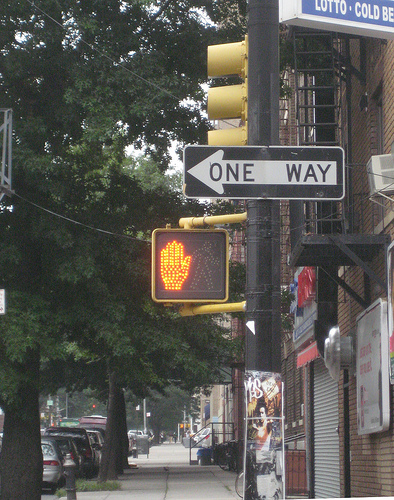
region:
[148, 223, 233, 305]
pedestrian Don't Walk signal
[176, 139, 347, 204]
black and white sign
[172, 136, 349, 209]
black and white rectangular One Way sign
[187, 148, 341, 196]
white arrow pointing left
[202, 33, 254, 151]
yellow traffic signal on pole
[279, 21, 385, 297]
metal fire escape on side of building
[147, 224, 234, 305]
Stop sign for padestrians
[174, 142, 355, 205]
Black and white one way sign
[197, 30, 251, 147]
Traffic signal for vehicles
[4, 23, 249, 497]
Shady trees on the sidewalk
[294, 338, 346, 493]
Metal shutter of the store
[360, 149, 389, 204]
Window airconditioner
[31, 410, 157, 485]
Cars parked near sidewalk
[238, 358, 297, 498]
Poster on black pole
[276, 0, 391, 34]
Store sign for lotto and cold beer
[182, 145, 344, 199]
a one way sign on a post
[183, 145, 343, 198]
a black sign under the traffic lights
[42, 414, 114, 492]
cars parked on the side of the road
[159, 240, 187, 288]
sign of a hand shown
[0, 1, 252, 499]
large green trees lining the street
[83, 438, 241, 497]
a gray, empty sidewalk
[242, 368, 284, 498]
a poster on the side of the post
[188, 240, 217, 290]
a man next to the hand sign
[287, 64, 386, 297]
balcony on the side of the building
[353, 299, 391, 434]
a large white sign on the side of the building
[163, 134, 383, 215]
One of the signs on the pole says "One Way"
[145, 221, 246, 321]
The walk or dont walk sign is lit up with dont walk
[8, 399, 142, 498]
There are cars parked along the curb on this street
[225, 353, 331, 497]
There is a sign with graffiti on it on the pole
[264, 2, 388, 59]
A business is on this corner called Lotto-Cold beer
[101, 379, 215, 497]
The sidewalk is empty of people.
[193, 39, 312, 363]
A stop light is on this pole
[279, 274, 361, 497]
A garage door on the street is steel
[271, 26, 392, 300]
There is a staircase outside of the building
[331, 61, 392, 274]
The building is brick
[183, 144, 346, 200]
a one way traffic sign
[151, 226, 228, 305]
a pedestrian crossing signal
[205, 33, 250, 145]
a traffic light on the post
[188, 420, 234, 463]
a hand rail on the steps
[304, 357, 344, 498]
a security garage door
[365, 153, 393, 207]
a wall air conditioner unit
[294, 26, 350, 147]
an emergency fire escape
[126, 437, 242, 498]
a grey concrete sidewalk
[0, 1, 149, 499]
trees lining the walkway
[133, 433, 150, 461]
a sealed trash can on the sidewalk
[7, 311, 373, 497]
sidewalk between trees and buildings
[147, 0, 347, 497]
black pole with poster, traffic lights and sign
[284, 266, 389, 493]
signs near closed metal gate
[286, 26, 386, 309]
black fire escape on side of building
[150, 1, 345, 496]
traffic pole posted near brick building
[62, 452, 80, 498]
grey fire hydrant posted on curbside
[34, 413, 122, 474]
Cars parked by a tree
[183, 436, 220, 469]
A trashcan by stairs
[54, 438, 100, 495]
Fire hydrant next to a car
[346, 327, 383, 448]
A white sign with red writing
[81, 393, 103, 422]
A stop light in the distance that is read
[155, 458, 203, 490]
A bird on sidewalk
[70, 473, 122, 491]
Grass growing on the sidewalk